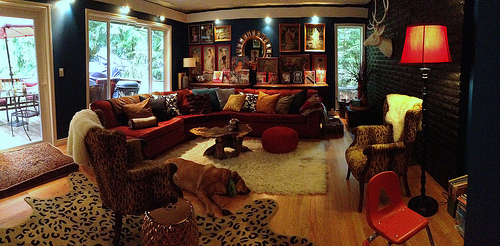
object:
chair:
[359, 171, 435, 246]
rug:
[0, 171, 314, 246]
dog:
[159, 157, 251, 218]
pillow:
[123, 97, 154, 119]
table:
[189, 118, 253, 161]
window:
[87, 19, 170, 110]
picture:
[279, 23, 301, 52]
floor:
[248, 110, 464, 245]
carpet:
[0, 173, 146, 245]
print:
[77, 199, 84, 204]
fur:
[172, 160, 219, 186]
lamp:
[399, 25, 452, 217]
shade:
[399, 24, 451, 63]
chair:
[66, 109, 203, 246]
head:
[362, 32, 392, 58]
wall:
[361, 0, 468, 191]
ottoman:
[261, 126, 300, 155]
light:
[159, 15, 165, 22]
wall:
[50, 0, 90, 141]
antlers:
[362, 0, 389, 47]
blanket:
[66, 109, 106, 166]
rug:
[150, 135, 328, 197]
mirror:
[236, 30, 273, 58]